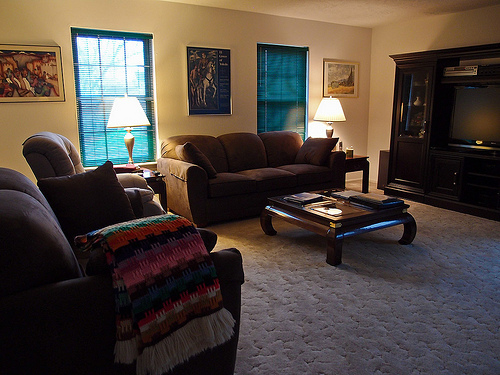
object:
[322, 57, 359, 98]
picture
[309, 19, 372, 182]
wall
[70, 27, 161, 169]
window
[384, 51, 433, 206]
stand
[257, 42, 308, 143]
window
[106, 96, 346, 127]
lampshades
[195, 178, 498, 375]
carpet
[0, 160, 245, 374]
sofa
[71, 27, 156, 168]
blinds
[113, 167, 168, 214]
end table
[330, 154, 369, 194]
end table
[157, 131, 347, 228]
sofa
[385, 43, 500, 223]
cabinet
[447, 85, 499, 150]
television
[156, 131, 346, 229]
couch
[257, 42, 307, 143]
blinds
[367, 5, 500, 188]
wall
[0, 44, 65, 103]
painting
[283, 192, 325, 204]
magazine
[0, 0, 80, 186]
wall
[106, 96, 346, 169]
lamps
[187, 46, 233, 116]
artwork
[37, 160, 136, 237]
throw pillow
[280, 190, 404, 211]
books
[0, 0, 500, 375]
living room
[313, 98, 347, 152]
lamp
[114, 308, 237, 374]
fringe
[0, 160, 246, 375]
chair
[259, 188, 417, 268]
coffe table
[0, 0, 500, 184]
wall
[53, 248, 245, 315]
arm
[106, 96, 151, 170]
lamp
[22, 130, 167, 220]
chair